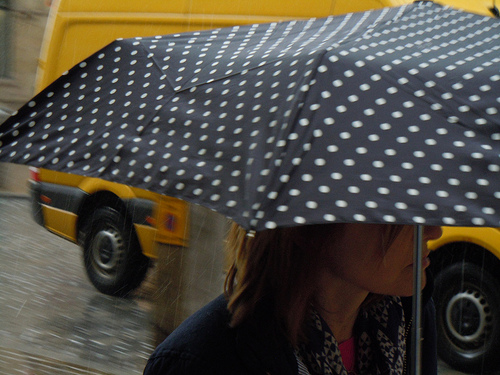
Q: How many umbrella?
A: One.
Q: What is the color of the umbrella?
A: Black and white.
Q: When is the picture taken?
A: Daytime.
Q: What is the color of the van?
A: Yellow.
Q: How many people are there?
A: 1.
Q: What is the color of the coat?
A: Blue.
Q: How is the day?
A: Rainy.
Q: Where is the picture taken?
A: On the street.